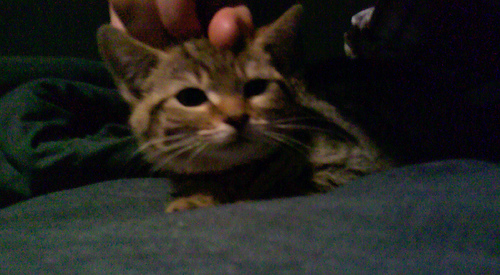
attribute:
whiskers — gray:
[132, 121, 328, 168]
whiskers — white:
[126, 130, 212, 173]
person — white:
[109, 0, 256, 47]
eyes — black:
[171, 76, 276, 113]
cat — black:
[93, 17, 428, 232]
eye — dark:
[174, 77, 204, 107]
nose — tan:
[223, 102, 247, 123]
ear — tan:
[88, 19, 165, 104]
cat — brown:
[93, 4, 396, 217]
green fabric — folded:
[0, 58, 174, 195]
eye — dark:
[169, 75, 209, 111]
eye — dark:
[240, 70, 271, 100]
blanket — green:
[6, 29, 161, 210]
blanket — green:
[7, 39, 168, 212]